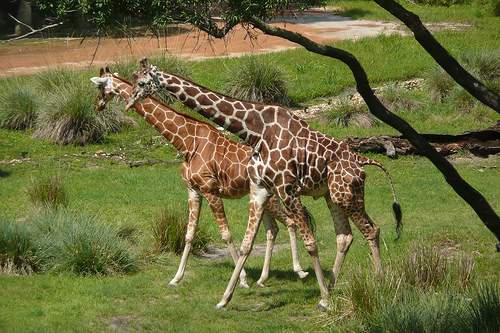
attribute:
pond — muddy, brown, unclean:
[1, 21, 360, 71]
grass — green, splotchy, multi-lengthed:
[3, 65, 498, 332]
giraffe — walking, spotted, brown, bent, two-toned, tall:
[127, 59, 406, 311]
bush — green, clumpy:
[34, 79, 144, 147]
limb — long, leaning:
[365, 0, 500, 122]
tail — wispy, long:
[357, 154, 419, 247]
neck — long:
[125, 53, 268, 155]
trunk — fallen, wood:
[308, 119, 499, 161]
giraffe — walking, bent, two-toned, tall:
[82, 54, 313, 294]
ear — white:
[83, 69, 114, 90]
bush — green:
[32, 210, 135, 280]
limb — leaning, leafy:
[160, 2, 498, 253]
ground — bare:
[275, 1, 444, 43]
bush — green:
[224, 53, 290, 113]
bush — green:
[1, 77, 42, 133]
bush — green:
[146, 203, 211, 262]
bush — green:
[23, 170, 82, 212]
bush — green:
[1, 212, 58, 279]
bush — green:
[368, 282, 499, 332]